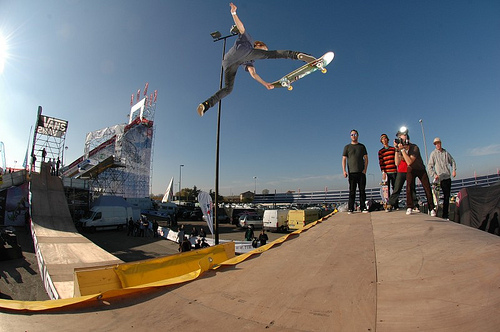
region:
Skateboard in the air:
[260, 48, 347, 89]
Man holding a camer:
[393, 118, 414, 165]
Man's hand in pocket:
[356, 138, 368, 185]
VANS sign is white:
[40, 113, 70, 137]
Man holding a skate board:
[374, 146, 390, 210]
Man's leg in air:
[195, 52, 240, 117]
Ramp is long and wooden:
[27, 170, 114, 298]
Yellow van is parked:
[287, 204, 322, 231]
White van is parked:
[258, 198, 286, 239]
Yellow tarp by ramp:
[4, 235, 256, 292]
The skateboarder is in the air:
[190, 12, 350, 119]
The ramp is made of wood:
[19, 166, 227, 316]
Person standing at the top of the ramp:
[338, 116, 375, 220]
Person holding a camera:
[386, 116, 438, 215]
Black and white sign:
[29, 113, 76, 140]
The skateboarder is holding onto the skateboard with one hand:
[190, 8, 348, 115]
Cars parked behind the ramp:
[226, 196, 324, 236]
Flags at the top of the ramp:
[115, 82, 165, 110]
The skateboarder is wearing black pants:
[183, 3, 341, 125]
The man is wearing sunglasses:
[334, 123, 369, 162]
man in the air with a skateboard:
[192, 11, 335, 118]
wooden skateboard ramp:
[21, 168, 237, 296]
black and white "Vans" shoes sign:
[33, 104, 73, 142]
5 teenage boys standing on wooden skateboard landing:
[337, 122, 461, 217]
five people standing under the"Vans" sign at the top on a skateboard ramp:
[24, 105, 71, 202]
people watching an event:
[119, 205, 277, 262]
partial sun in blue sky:
[0, 2, 176, 81]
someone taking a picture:
[390, 124, 436, 222]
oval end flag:
[191, 184, 216, 236]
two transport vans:
[257, 206, 311, 231]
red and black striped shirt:
[375, 128, 398, 175]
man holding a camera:
[389, 121, 409, 154]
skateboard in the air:
[263, 51, 352, 100]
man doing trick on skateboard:
[195, 8, 328, 113]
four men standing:
[339, 121, 465, 226]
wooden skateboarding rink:
[22, 176, 106, 291]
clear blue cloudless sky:
[371, 20, 469, 87]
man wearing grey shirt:
[416, 132, 460, 183]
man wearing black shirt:
[339, 129, 373, 189]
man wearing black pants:
[336, 126, 371, 207]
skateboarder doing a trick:
[206, 9, 369, 127]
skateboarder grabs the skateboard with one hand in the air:
[206, 24, 334, 124]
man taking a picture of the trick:
[381, 135, 435, 156]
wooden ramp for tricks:
[26, 155, 193, 325]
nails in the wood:
[368, 231, 386, 329]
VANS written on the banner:
[34, 103, 79, 143]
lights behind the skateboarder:
[190, 19, 244, 237]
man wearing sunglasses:
[342, 119, 380, 149]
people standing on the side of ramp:
[32, 143, 72, 186]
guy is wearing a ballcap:
[430, 139, 447, 152]